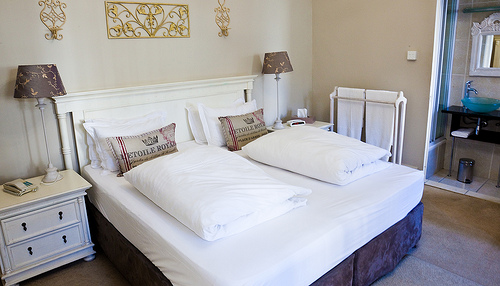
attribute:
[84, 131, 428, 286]
bed — large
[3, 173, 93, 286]
nightstand — white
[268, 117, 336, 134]
nightstand — white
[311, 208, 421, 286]
bedskirt — dark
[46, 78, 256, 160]
headboard — white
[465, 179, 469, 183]
foot pedal — white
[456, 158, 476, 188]
trashcan — silver, metal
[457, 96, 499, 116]
sink bowl — light blue, blue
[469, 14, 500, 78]
mirror — framed, white, white framed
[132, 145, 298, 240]
bedding — folded, white, large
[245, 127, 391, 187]
bedding — folded, white, large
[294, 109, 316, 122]
box of tissues — brown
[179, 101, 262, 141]
pillows — white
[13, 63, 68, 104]
lamp cover — brown, dark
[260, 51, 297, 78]
lamp cover — brown, dark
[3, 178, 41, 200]
telephone — beige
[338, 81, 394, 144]
towels — white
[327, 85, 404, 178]
rack — white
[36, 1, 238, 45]
decorations — gold, small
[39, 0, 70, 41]
decoration — pineapple shaped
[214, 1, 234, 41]
decoration — pineapple shaped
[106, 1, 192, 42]
decoration — gold, rectangular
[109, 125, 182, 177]
decorative pillow — gray, red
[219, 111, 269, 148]
decorative pillow — gray, red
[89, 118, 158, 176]
pillows — white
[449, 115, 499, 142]
shelf — black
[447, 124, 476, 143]
towel — folded, white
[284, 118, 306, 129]
alarm clock — white